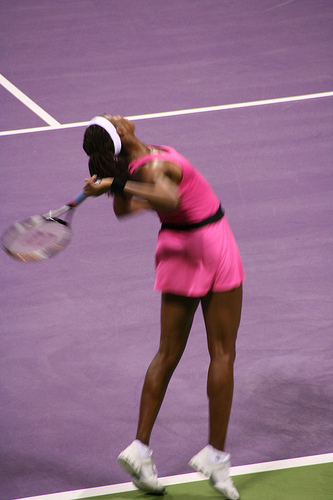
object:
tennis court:
[0, 0, 333, 499]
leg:
[136, 294, 197, 442]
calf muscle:
[144, 360, 167, 398]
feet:
[192, 444, 238, 498]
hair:
[82, 127, 112, 176]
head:
[82, 112, 136, 156]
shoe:
[115, 438, 167, 498]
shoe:
[187, 443, 240, 499]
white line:
[139, 89, 333, 123]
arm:
[105, 177, 180, 208]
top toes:
[158, 477, 167, 494]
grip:
[85, 174, 101, 198]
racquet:
[2, 176, 100, 264]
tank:
[156, 164, 195, 194]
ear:
[116, 126, 127, 135]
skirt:
[149, 220, 252, 300]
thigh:
[199, 281, 244, 339]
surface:
[0, 1, 333, 498]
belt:
[160, 201, 224, 230]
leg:
[202, 281, 243, 446]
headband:
[85, 115, 122, 159]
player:
[79, 116, 244, 500]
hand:
[83, 172, 111, 197]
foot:
[122, 443, 164, 491]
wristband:
[108, 174, 129, 194]